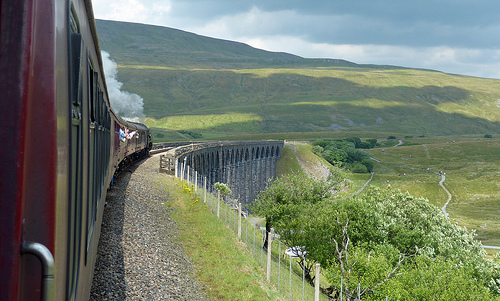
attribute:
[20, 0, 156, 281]
train — red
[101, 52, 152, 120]
smoke — white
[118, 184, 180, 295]
rocks — small, grey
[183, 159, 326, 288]
fence — grey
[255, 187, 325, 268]
tree — green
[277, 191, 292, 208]
leaves — green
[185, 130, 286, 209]
bridge — tall, grey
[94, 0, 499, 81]
sky — cloudy, blue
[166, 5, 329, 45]
clouds — dark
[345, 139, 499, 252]
grass — green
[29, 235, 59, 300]
pole — metal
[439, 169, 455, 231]
water — stream